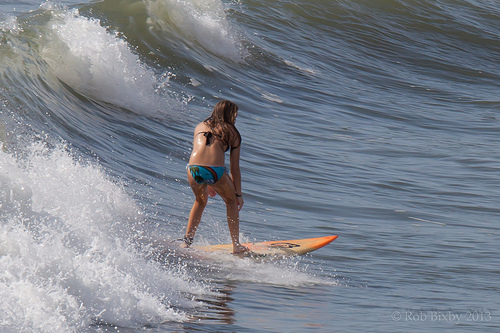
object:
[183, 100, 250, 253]
woman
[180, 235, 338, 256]
surfboard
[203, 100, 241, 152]
hair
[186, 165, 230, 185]
bottoms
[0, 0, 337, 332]
wave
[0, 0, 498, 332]
water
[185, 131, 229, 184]
bikini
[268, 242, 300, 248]
design